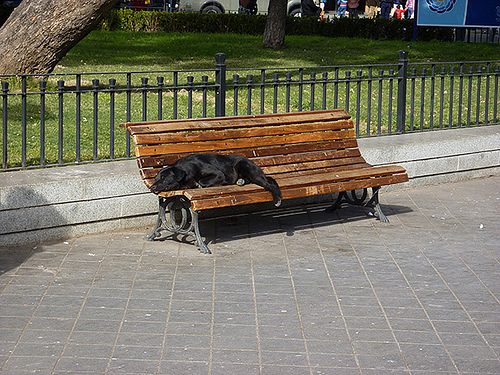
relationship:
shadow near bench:
[0, 179, 77, 286] [104, 102, 417, 251]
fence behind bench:
[308, 64, 497, 137] [25, 43, 411, 244]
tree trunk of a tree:
[3, 2, 129, 73] [0, 0, 169, 80]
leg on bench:
[150, 202, 207, 252] [118, 105, 409, 254]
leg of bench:
[146, 195, 213, 254] [118, 105, 409, 254]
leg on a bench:
[146, 195, 213, 254] [119, 106, 409, 211]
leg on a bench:
[327, 185, 388, 222] [119, 106, 409, 211]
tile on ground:
[0, 167, 496, 373] [10, 205, 497, 374]